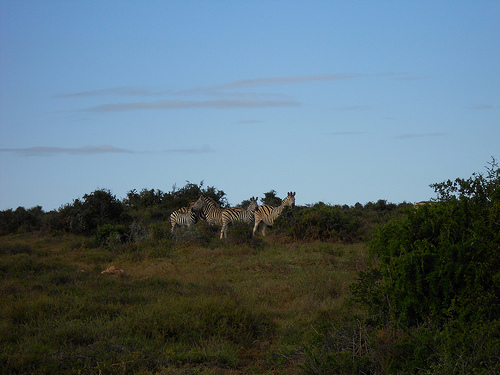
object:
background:
[0, 155, 499, 246]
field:
[0, 229, 369, 375]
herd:
[253, 191, 297, 237]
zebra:
[252, 191, 297, 237]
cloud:
[0, 142, 138, 160]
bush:
[347, 155, 500, 324]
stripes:
[255, 205, 281, 224]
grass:
[0, 230, 371, 374]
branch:
[309, 321, 338, 350]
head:
[285, 191, 296, 209]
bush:
[285, 201, 365, 242]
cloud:
[77, 98, 302, 114]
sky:
[1, 0, 498, 214]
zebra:
[218, 196, 260, 240]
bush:
[394, 316, 499, 375]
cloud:
[321, 131, 369, 137]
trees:
[82, 187, 126, 233]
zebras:
[168, 199, 200, 234]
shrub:
[173, 220, 215, 251]